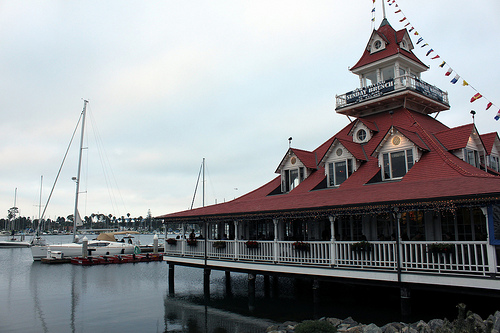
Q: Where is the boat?
A: On the water.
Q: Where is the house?
A: NExt to the water.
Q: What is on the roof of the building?
A: Streamers.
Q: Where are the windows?
A: On the building.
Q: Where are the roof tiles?
A: On the roofs.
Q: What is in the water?
A: Boats.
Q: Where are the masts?
A: On the boats.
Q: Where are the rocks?
A: In front of the house.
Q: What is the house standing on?
A: The water.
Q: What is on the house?
A: Railings.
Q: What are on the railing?
A: Flowers.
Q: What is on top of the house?
A: Railings.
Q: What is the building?
A: Restaurant.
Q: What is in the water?
A: Boats.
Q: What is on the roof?
A: Red tiles.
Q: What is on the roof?
A: Flags.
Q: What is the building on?
A: Stilts.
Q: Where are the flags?
A: On the rope.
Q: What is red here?
A: The building.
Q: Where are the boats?
A: In the water.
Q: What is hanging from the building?
A: Flags.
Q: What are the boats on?
A: The water.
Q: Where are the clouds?
A: In the sky.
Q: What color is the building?
A: Red and white.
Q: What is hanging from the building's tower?
A: Flags.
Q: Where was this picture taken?
A: The waterfront.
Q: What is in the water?
A: Boats.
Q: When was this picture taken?
A: The daytime.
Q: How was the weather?
A: Overcast.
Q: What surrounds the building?
A: A white railing.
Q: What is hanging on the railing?
A: Plant pots.